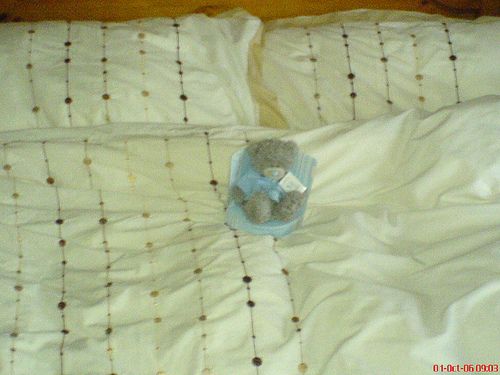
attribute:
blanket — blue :
[2, 21, 495, 371]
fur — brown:
[225, 133, 317, 236]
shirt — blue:
[234, 170, 286, 203]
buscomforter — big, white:
[5, 3, 498, 373]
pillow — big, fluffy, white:
[247, 17, 496, 109]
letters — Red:
[445, 358, 462, 373]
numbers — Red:
[460, 362, 498, 372]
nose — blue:
[272, 171, 279, 176]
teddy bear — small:
[221, 133, 316, 214]